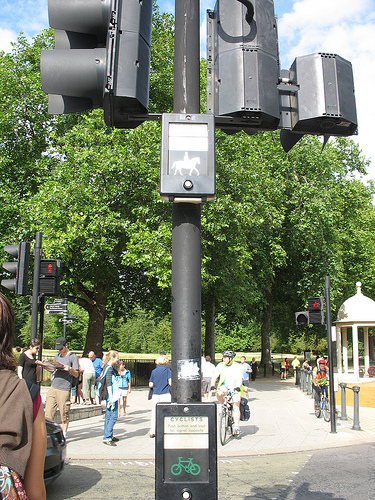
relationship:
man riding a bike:
[211, 336, 249, 406] [213, 387, 238, 445]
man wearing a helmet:
[211, 336, 249, 406] [214, 343, 239, 368]